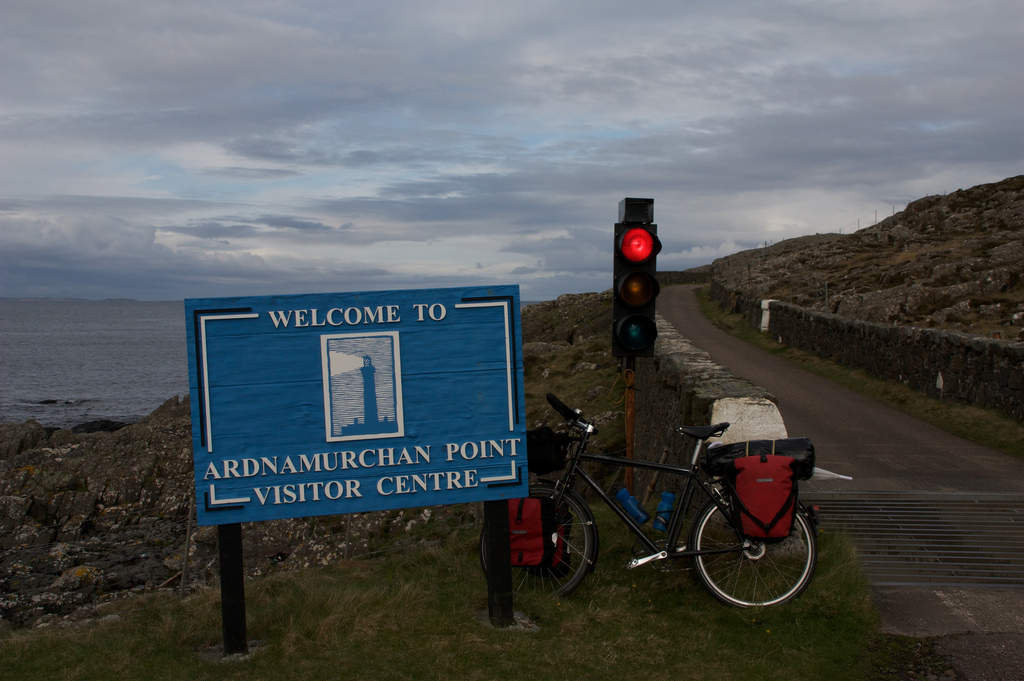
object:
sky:
[0, 0, 1024, 301]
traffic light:
[612, 197, 663, 356]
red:
[622, 228, 652, 261]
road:
[656, 282, 1024, 681]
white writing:
[268, 303, 446, 328]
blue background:
[184, 284, 529, 526]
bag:
[736, 454, 799, 543]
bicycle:
[481, 393, 815, 609]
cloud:
[158, 141, 289, 168]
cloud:
[265, 184, 380, 208]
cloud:
[513, 18, 822, 131]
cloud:
[661, 170, 1017, 239]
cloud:
[0, 143, 173, 201]